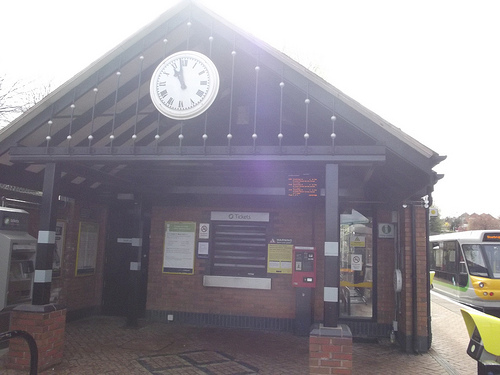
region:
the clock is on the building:
[149, 49, 219, 121]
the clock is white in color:
[150, 49, 223, 119]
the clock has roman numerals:
[155, 53, 206, 112]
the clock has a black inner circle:
[157, 50, 210, 112]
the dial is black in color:
[171, 58, 186, 87]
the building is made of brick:
[58, 183, 428, 344]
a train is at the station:
[418, 228, 495, 314]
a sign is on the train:
[481, 233, 498, 244]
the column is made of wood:
[316, 169, 348, 329]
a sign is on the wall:
[160, 218, 193, 272]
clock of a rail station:
[145, 47, 228, 135]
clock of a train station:
[141, 47, 240, 126]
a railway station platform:
[17, 16, 497, 373]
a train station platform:
[0, 0, 495, 360]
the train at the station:
[429, 209, 499, 316]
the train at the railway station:
[424, 209, 499, 324]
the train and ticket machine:
[428, 216, 498, 373]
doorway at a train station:
[92, 202, 172, 332]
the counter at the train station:
[152, 199, 319, 304]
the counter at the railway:
[150, 189, 310, 357]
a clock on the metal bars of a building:
[153, 53, 215, 114]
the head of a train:
[440, 232, 495, 307]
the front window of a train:
[470, 243, 497, 269]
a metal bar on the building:
[275, 87, 289, 154]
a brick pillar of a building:
[401, 209, 428, 349]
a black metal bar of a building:
[321, 178, 346, 330]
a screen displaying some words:
[283, 165, 322, 207]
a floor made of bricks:
[91, 326, 286, 371]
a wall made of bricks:
[150, 270, 280, 317]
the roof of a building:
[198, 5, 440, 155]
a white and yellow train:
[436, 230, 498, 292]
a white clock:
[147, 50, 217, 115]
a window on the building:
[203, 212, 273, 283]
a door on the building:
[103, 207, 143, 313]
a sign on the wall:
[78, 220, 98, 268]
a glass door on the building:
[340, 199, 377, 327]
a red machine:
[293, 243, 313, 331]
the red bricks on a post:
[308, 337, 355, 366]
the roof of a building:
[34, 26, 425, 181]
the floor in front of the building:
[76, 320, 274, 365]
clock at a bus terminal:
[31, 19, 444, 356]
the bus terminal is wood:
[71, 18, 477, 342]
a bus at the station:
[431, 217, 498, 319]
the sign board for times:
[179, 192, 289, 294]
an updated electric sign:
[280, 145, 341, 226]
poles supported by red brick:
[30, 176, 121, 367]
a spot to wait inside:
[319, 189, 499, 371]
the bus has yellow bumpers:
[448, 208, 497, 340]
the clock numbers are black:
[137, 45, 229, 136]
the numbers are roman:
[109, 26, 262, 153]